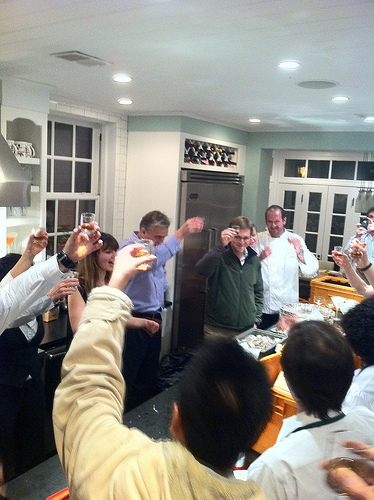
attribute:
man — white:
[358, 210, 372, 241]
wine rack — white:
[174, 141, 239, 168]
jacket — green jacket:
[194, 240, 262, 328]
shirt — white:
[248, 226, 319, 316]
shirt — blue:
[121, 234, 177, 316]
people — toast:
[86, 203, 322, 335]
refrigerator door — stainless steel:
[183, 185, 217, 343]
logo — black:
[187, 191, 198, 200]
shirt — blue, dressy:
[116, 228, 181, 310]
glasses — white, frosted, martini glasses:
[77, 209, 98, 234]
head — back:
[176, 340, 271, 467]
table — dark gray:
[42, 316, 323, 498]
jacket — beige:
[86, 298, 118, 411]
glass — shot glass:
[134, 238, 160, 273]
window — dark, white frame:
[46, 113, 99, 194]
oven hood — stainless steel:
[0, 134, 31, 207]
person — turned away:
[65, 241, 273, 498]